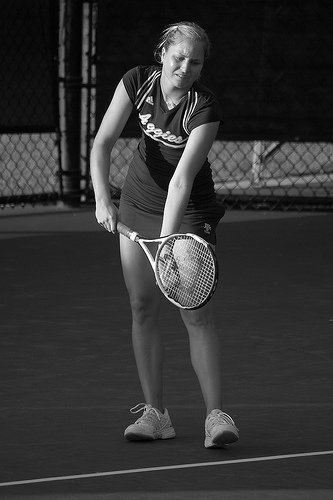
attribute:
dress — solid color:
[117, 66, 217, 246]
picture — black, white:
[2, 2, 331, 497]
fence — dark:
[0, 1, 331, 213]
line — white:
[0, 450, 331, 486]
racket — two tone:
[107, 214, 219, 310]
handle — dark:
[93, 209, 140, 241]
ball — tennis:
[158, 267, 177, 288]